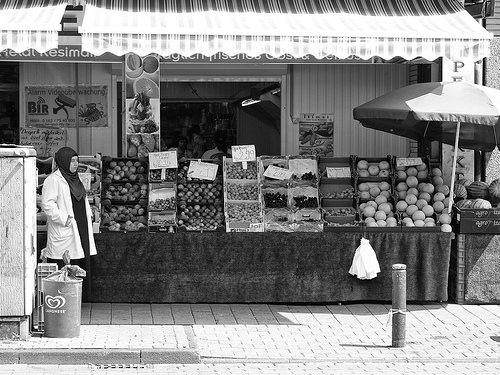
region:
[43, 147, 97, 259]
this is a lady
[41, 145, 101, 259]
the lady is standing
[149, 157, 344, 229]
she is selling groceries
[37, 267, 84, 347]
this is a dust bin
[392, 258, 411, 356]
this is a pole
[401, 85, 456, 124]
this is an umbrella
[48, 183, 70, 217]
the coat is white in color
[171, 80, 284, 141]
the door is open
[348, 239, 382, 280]
these are the paper bags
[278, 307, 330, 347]
the road is tiled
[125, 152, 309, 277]
plenty fruits on shelf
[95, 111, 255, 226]
plenty fruits on shelf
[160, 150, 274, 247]
plenty fruits on shelf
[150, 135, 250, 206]
plenty fruits on shelf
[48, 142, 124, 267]
woman standing by fruit stand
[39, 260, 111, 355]
garbage can near fruit stand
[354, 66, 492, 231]
umbrella in the fruit stand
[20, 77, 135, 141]
sign behind fruit sign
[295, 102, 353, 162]
sign behind fruit stand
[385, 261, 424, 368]
post in the sidewalk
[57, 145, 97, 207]
scarf on the woman's head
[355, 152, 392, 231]
fruit in the fruit stand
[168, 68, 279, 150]
doorway behind the fruit stand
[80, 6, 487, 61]
awning above the fruit stand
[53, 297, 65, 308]
the heart is drawn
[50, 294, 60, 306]
the heart is drawn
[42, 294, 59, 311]
the heart is drawn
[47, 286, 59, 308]
the heart is drawn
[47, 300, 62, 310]
the heart is drawn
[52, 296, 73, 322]
the heart is drawn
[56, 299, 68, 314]
the heart is drawn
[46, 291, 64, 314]
the heart is drawn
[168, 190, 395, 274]
plenty fruits on shelf